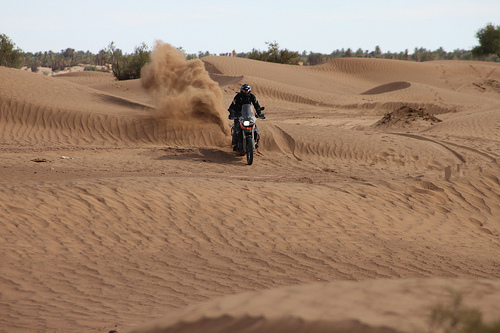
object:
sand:
[2, 37, 494, 327]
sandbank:
[280, 105, 471, 177]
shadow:
[146, 130, 243, 170]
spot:
[356, 68, 410, 100]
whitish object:
[61, 155, 73, 160]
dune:
[0, 40, 496, 333]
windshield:
[239, 102, 255, 120]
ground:
[428, 107, 467, 149]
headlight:
[243, 120, 250, 126]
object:
[50, 143, 81, 170]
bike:
[230, 104, 260, 164]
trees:
[308, 51, 317, 65]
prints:
[366, 122, 441, 222]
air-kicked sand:
[136, 38, 232, 144]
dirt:
[126, 57, 301, 204]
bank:
[18, 100, 178, 160]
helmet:
[240, 83, 251, 92]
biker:
[227, 83, 261, 150]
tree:
[0, 31, 25, 67]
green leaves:
[0, 36, 15, 62]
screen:
[241, 105, 255, 115]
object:
[61, 154, 74, 162]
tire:
[240, 127, 254, 165]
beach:
[0, 37, 495, 319]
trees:
[123, 43, 152, 81]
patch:
[12, 98, 497, 203]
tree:
[468, 22, 497, 58]